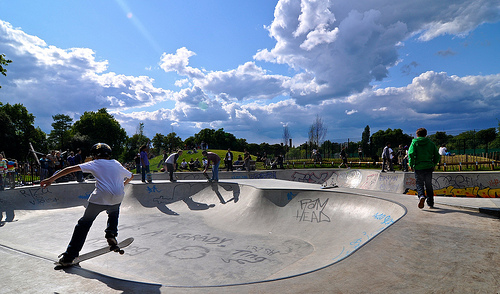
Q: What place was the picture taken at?
A: It was taken at the skate park.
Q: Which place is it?
A: It is a skate park.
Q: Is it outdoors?
A: Yes, it is outdoors.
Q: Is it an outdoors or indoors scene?
A: It is outdoors.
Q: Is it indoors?
A: No, it is outdoors.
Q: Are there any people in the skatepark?
A: Yes, there is a person in the skatepark.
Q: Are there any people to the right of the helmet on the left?
A: Yes, there is a person to the right of the helmet.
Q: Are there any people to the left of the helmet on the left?
A: No, the person is to the right of the helmet.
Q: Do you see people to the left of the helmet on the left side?
A: No, the person is to the right of the helmet.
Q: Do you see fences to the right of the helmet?
A: No, there is a person to the right of the helmet.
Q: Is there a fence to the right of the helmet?
A: No, there is a person to the right of the helmet.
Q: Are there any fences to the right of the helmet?
A: No, there is a person to the right of the helmet.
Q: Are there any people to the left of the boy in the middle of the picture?
A: Yes, there is a person to the left of the boy.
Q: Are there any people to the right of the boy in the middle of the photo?
A: No, the person is to the left of the boy.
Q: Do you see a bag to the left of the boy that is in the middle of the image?
A: No, there is a person to the left of the boy.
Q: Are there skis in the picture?
A: No, there are no skis.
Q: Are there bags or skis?
A: No, there are no skis or bags.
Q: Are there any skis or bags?
A: No, there are no skis or bags.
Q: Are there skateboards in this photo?
A: Yes, there is a skateboard.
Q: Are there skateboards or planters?
A: Yes, there is a skateboard.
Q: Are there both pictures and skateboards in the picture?
A: No, there is a skateboard but no pictures.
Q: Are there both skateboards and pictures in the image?
A: No, there is a skateboard but no pictures.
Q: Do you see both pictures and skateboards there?
A: No, there is a skateboard but no pictures.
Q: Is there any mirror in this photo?
A: No, there are no mirrors.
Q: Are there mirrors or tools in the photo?
A: No, there are no mirrors or tools.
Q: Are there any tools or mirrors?
A: No, there are no mirrors or tools.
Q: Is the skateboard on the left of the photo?
A: Yes, the skateboard is on the left of the image.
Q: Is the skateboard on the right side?
A: No, the skateboard is on the left of the image.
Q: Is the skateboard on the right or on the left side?
A: The skateboard is on the left of the image.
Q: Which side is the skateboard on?
A: The skateboard is on the left of the image.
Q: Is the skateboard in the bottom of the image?
A: Yes, the skateboard is in the bottom of the image.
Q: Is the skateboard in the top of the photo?
A: No, the skateboard is in the bottom of the image.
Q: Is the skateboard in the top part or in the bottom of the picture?
A: The skateboard is in the bottom of the image.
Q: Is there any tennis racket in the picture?
A: No, there are no rackets.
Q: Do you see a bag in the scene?
A: No, there are no bags.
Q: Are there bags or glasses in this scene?
A: No, there are no bags or glasses.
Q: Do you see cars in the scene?
A: No, there are no cars.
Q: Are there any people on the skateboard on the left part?
A: Yes, there is a person on the skateboard.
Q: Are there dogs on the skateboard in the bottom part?
A: No, there is a person on the skateboard.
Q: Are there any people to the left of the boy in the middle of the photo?
A: Yes, there is a person to the left of the boy.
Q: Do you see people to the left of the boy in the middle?
A: Yes, there is a person to the left of the boy.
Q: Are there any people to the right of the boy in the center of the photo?
A: No, the person is to the left of the boy.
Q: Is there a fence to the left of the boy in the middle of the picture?
A: No, there is a person to the left of the boy.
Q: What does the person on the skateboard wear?
A: The person wears a helmet.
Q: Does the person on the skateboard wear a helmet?
A: Yes, the person wears a helmet.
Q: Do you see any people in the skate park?
A: Yes, there is a person in the skate park.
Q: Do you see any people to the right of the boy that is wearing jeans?
A: Yes, there is a person to the right of the boy.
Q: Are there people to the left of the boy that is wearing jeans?
A: No, the person is to the right of the boy.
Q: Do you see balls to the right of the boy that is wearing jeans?
A: No, there is a person to the right of the boy.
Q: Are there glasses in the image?
A: No, there are no glasses.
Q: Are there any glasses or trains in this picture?
A: No, there are no glasses or trains.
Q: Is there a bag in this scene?
A: No, there are no bags.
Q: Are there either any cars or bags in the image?
A: No, there are no bags or cars.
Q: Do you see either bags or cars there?
A: No, there are no bags or cars.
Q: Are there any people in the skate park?
A: Yes, there are people in the skate park.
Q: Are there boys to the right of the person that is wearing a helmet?
A: Yes, there is a boy to the right of the person.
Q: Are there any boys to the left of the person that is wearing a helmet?
A: No, the boy is to the right of the person.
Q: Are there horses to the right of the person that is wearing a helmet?
A: No, there is a boy to the right of the person.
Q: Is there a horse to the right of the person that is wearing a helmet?
A: No, there is a boy to the right of the person.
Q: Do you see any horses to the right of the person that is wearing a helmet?
A: No, there is a boy to the right of the person.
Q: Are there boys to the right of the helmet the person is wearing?
A: Yes, there is a boy to the right of the helmet.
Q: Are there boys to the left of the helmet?
A: No, the boy is to the right of the helmet.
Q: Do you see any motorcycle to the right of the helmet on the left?
A: No, there is a boy to the right of the helmet.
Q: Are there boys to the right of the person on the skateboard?
A: Yes, there is a boy to the right of the person.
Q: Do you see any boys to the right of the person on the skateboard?
A: Yes, there is a boy to the right of the person.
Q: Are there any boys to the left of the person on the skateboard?
A: No, the boy is to the right of the person.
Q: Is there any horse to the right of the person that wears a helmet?
A: No, there is a boy to the right of the person.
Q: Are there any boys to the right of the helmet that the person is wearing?
A: Yes, there is a boy to the right of the helmet.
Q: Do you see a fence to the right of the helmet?
A: No, there is a boy to the right of the helmet.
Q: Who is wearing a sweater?
A: The boy is wearing a sweater.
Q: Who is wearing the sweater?
A: The boy is wearing a sweater.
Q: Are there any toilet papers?
A: No, there are no toilet papers.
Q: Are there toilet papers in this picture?
A: No, there are no toilet papers.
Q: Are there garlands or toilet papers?
A: No, there are no toilet papers or garlands.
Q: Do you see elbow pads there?
A: No, there are no elbow pads.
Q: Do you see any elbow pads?
A: No, there are no elbow pads.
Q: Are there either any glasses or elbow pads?
A: No, there are no elbow pads or glasses.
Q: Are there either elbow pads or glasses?
A: No, there are no elbow pads or glasses.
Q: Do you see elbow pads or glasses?
A: No, there are no elbow pads or glasses.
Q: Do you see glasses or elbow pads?
A: No, there are no elbow pads or glasses.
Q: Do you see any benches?
A: No, there are no benches.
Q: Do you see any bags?
A: No, there are no bags.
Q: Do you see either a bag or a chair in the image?
A: No, there are no bags or chairs.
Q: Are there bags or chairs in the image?
A: No, there are no bags or chairs.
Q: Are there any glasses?
A: No, there are no glasses.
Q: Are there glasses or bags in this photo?
A: No, there are no glasses or bags.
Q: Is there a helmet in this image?
A: Yes, there is a helmet.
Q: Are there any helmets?
A: Yes, there is a helmet.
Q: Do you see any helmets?
A: Yes, there is a helmet.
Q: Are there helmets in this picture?
A: Yes, there is a helmet.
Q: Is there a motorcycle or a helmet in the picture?
A: Yes, there is a helmet.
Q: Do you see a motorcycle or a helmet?
A: Yes, there is a helmet.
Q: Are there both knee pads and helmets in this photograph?
A: No, there is a helmet but no knee pads.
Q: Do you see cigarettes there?
A: No, there are no cigarettes.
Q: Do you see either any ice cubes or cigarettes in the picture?
A: No, there are no cigarettes or ice cubes.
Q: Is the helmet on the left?
A: Yes, the helmet is on the left of the image.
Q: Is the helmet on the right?
A: No, the helmet is on the left of the image.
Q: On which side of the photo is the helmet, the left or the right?
A: The helmet is on the left of the image.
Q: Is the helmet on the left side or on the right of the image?
A: The helmet is on the left of the image.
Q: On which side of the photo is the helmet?
A: The helmet is on the left of the image.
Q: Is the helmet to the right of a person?
A: No, the helmet is to the left of a person.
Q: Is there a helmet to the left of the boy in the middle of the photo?
A: Yes, there is a helmet to the left of the boy.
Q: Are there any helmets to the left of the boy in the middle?
A: Yes, there is a helmet to the left of the boy.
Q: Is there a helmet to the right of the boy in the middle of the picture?
A: No, the helmet is to the left of the boy.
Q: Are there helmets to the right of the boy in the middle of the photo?
A: No, the helmet is to the left of the boy.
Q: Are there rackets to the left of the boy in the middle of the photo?
A: No, there is a helmet to the left of the boy.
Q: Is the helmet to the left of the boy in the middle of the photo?
A: Yes, the helmet is to the left of the boy.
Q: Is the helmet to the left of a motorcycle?
A: No, the helmet is to the left of the boy.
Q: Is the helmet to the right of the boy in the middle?
A: No, the helmet is to the left of the boy.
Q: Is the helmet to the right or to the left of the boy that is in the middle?
A: The helmet is to the left of the boy.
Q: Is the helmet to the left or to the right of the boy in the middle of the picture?
A: The helmet is to the left of the boy.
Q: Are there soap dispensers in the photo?
A: No, there are no soap dispensers.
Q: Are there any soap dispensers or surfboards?
A: No, there are no soap dispensers or surfboards.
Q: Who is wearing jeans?
A: The boy is wearing jeans.